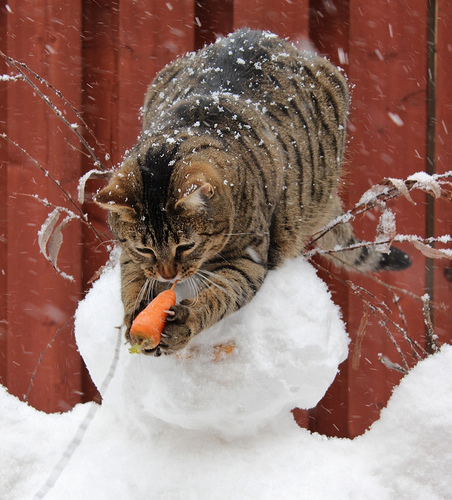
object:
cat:
[89, 27, 412, 357]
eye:
[176, 241, 198, 257]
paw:
[159, 300, 194, 355]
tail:
[309, 202, 410, 274]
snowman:
[0, 240, 451, 498]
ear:
[171, 187, 213, 215]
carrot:
[126, 279, 179, 354]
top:
[126, 331, 156, 356]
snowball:
[70, 245, 350, 437]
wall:
[1, 4, 451, 440]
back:
[141, 28, 330, 140]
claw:
[159, 308, 177, 317]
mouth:
[169, 337, 240, 361]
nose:
[162, 267, 180, 281]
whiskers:
[189, 267, 248, 312]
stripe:
[138, 151, 171, 247]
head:
[107, 149, 230, 283]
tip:
[373, 247, 411, 272]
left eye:
[132, 243, 154, 255]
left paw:
[122, 301, 148, 339]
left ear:
[94, 185, 139, 213]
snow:
[163, 132, 177, 149]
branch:
[301, 207, 451, 273]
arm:
[364, 341, 451, 497]